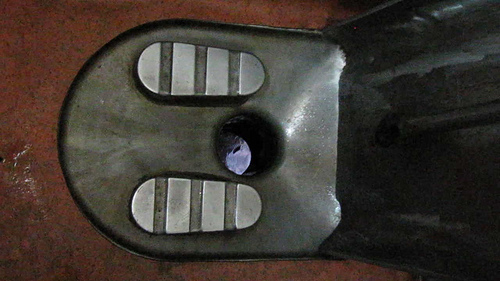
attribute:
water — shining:
[231, 141, 253, 169]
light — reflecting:
[280, 86, 321, 142]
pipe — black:
[364, 92, 496, 159]